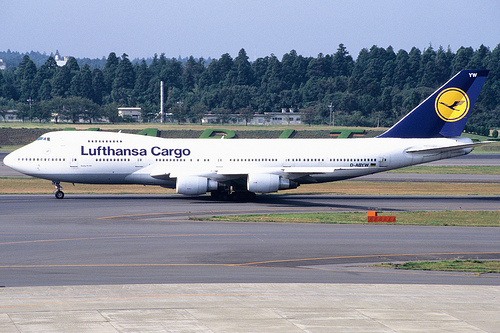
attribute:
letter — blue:
[96, 138, 103, 155]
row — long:
[18, 156, 378, 162]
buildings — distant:
[1, 80, 311, 125]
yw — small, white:
[468, 71, 476, 80]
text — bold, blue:
[80, 143, 149, 158]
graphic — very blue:
[391, 67, 478, 139]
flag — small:
[369, 162, 379, 169]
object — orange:
[365, 205, 397, 226]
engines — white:
[171, 168, 291, 208]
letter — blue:
[146, 140, 161, 160]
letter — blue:
[73, 141, 91, 156]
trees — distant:
[3, 39, 497, 124]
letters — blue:
[81, 143, 193, 160]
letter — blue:
[86, 133, 146, 170]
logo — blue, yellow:
[431, 85, 472, 125]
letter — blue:
[88, 144, 98, 159]